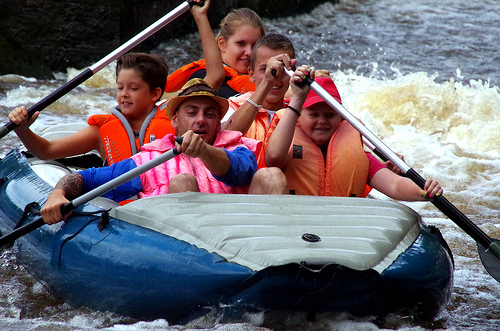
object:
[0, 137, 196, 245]
handle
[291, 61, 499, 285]
paddle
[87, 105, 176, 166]
vest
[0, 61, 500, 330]
wave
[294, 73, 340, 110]
red hat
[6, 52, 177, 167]
boy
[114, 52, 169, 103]
hair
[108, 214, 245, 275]
blue grey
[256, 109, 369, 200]
vest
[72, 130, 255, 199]
jacket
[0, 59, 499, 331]
rapids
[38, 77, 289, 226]
man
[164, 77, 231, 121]
hat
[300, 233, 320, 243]
port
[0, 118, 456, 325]
raft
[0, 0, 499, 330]
water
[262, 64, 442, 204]
boy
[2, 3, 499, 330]
sports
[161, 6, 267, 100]
girl